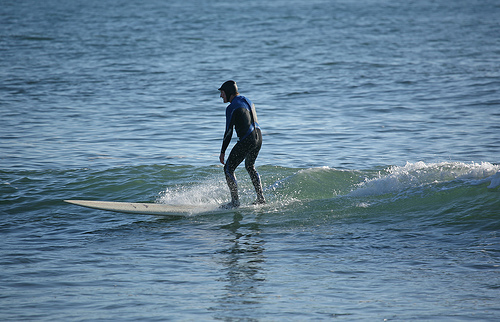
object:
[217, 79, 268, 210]
wet suit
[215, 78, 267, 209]
man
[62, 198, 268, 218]
surfboard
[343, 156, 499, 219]
wave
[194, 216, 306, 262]
light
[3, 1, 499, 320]
water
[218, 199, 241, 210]
feet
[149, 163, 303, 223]
spray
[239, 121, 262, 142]
stripes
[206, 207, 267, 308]
reflection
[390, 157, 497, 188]
top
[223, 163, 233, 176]
knee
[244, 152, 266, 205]
legs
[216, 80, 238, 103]
hat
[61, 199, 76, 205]
tip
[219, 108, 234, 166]
arm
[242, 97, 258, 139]
zipper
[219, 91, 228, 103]
face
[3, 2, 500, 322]
ocean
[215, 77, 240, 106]
head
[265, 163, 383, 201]
waves